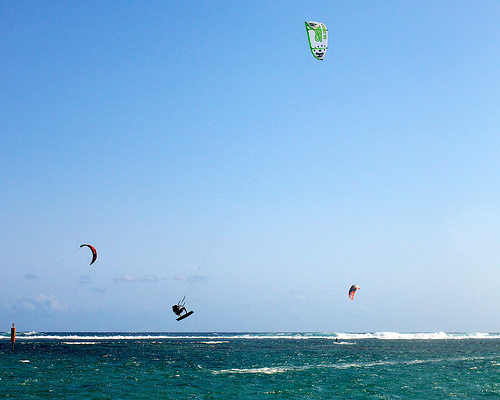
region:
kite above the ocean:
[63, 234, 132, 293]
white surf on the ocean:
[250, 320, 497, 352]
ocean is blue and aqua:
[52, 343, 434, 398]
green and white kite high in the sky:
[303, 8, 358, 151]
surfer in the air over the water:
[161, 268, 217, 335]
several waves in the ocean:
[102, 323, 497, 388]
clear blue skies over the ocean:
[7, 15, 462, 316]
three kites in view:
[24, 15, 404, 301]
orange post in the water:
[0, 308, 32, 361]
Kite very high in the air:
[11, 6, 494, 190]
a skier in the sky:
[165, 296, 202, 331]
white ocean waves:
[307, 331, 477, 356]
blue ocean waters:
[77, 343, 394, 387]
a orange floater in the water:
[7, 325, 17, 352]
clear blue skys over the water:
[31, 21, 224, 364]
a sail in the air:
[81, 236, 108, 281]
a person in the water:
[331, 333, 342, 354]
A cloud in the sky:
[14, 290, 89, 324]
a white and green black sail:
[302, 11, 336, 70]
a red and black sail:
[77, 238, 107, 277]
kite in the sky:
[73, 236, 107, 268]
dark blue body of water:
[2, 334, 486, 399]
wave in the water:
[327, 330, 479, 341]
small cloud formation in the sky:
[4, 267, 72, 329]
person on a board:
[165, 299, 200, 321]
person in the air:
[165, 299, 204, 324]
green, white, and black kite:
[304, 23, 331, 64]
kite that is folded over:
[79, 243, 99, 267]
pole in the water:
[9, 321, 19, 351]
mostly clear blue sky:
[4, 1, 492, 334]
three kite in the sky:
[58, 13, 377, 303]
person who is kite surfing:
[138, 10, 340, 352]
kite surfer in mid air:
[166, 295, 192, 325]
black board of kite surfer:
[172, 311, 194, 324]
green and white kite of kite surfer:
[301, 13, 337, 65]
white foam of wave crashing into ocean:
[10, 325, 498, 344]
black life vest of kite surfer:
[172, 305, 187, 312]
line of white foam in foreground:
[220, 348, 497, 385]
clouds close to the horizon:
[10, 263, 207, 326]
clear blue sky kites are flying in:
[20, 17, 497, 279]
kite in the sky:
[301, 14, 336, 70]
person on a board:
[158, 286, 203, 334]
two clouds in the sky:
[71, 238, 383, 303]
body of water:
[1, 321, 499, 398]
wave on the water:
[326, 328, 461, 341]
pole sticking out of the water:
[9, 321, 18, 346]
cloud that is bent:
[77, 241, 104, 268]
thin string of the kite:
[175, 53, 346, 305]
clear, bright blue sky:
[1, 3, 498, 340]